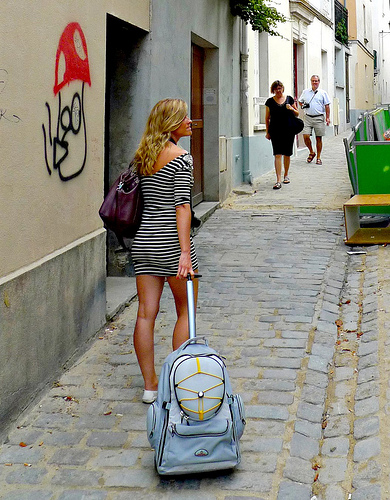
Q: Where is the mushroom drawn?
A: Wall.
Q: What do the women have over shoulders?
A: Handbags.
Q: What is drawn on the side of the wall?
A: Mushroom.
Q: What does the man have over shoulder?
A: Camera.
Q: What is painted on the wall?
A: Mushroom.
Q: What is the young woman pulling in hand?
A: Luggage.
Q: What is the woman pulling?
A: Suitcase.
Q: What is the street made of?
A: Stone.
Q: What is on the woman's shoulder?
A: A purse.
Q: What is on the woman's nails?
A: Nail polish.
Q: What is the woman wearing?
A: Dress.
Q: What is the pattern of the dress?
A: Stripes.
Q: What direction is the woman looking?
A: To the right.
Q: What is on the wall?
A: Graffiti.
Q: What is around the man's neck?
A: A camera.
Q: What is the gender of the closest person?
A: Female.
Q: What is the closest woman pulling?
A: Duffle bag.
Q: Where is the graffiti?
A: Wall.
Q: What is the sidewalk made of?
A: Cobblestone.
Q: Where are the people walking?
A: Sidewalk.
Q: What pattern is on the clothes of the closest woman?
A: Stripes.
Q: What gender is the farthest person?
A: Male.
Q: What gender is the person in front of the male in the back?
A: Female.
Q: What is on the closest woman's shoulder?
A: Purse.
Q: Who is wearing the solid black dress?
A: Woman in front of the man.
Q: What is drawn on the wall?
A: A mushroom.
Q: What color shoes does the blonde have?
A: White.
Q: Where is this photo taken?
A: In a alley way.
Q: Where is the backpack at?
A: Behind the blonde.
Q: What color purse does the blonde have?
A: Purple.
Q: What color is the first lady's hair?
A: Blonde.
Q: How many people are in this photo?
A: Three.